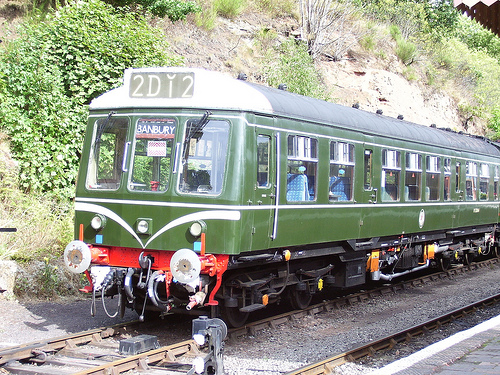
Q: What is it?
A: Train.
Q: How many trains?
A: 1.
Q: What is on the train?
A: People.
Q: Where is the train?
A: Tracks.